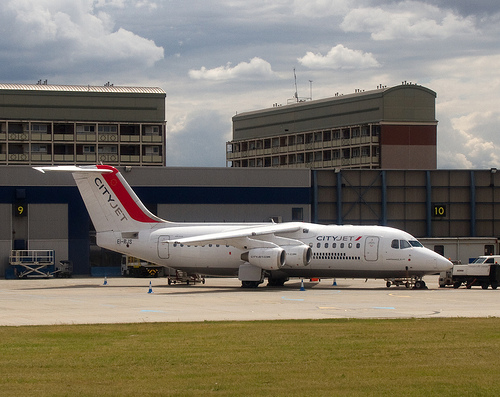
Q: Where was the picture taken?
A: It was taken at the airport.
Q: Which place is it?
A: It is an airport.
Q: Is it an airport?
A: Yes, it is an airport.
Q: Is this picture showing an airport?
A: Yes, it is showing an airport.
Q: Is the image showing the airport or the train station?
A: It is showing the airport.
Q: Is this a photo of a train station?
A: No, the picture is showing an airport.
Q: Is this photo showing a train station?
A: No, the picture is showing an airport.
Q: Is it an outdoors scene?
A: Yes, it is outdoors.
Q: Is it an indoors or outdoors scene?
A: It is outdoors.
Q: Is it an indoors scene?
A: No, it is outdoors.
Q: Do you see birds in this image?
A: No, there are no birds.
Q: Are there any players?
A: No, there are no players.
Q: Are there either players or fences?
A: No, there are no players or fences.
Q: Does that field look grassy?
A: Yes, the field is grassy.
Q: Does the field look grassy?
A: Yes, the field is grassy.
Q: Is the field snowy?
A: No, the field is grassy.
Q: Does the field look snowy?
A: No, the field is grassy.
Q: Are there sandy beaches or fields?
A: No, there is a field but it is grassy.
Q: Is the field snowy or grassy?
A: The field is grassy.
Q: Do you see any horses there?
A: No, there are no horses.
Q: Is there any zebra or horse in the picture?
A: No, there are no horses or zebras.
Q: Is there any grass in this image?
A: Yes, there is grass.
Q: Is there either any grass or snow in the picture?
A: Yes, there is grass.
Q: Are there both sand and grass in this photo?
A: No, there is grass but no sand.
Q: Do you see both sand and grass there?
A: No, there is grass but no sand.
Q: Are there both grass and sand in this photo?
A: No, there is grass but no sand.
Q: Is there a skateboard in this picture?
A: No, there are no skateboards.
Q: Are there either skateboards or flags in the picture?
A: No, there are no skateboards or flags.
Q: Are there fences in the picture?
A: No, there are no fences.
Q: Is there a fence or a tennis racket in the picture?
A: No, there are no fences or rackets.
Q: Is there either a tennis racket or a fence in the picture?
A: No, there are no fences or rackets.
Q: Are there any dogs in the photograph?
A: No, there are no dogs.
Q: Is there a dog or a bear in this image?
A: No, there are no dogs or bears.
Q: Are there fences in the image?
A: No, there are no fences.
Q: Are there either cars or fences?
A: No, there are no fences or cars.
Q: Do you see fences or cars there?
A: No, there are no fences or cars.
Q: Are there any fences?
A: No, there are no fences.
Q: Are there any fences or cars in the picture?
A: No, there are no fences or cars.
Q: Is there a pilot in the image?
A: No, there are no pilots.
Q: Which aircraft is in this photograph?
A: The aircraft is a jet.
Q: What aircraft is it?
A: The aircraft is a jet.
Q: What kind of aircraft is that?
A: That is a jet.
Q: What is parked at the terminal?
A: The jet is parked at the terminal.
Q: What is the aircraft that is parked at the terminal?
A: The aircraft is a jet.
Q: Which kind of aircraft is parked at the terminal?
A: The aircraft is a jet.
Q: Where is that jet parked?
A: The jet is parked at the terminal.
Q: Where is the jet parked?
A: The jet is parked at the terminal.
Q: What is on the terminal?
A: The jet is on the terminal.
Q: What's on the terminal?
A: The jet is on the terminal.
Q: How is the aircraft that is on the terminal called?
A: The aircraft is a jet.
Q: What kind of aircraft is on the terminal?
A: The aircraft is a jet.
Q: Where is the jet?
A: The jet is on the terminal.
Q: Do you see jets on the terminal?
A: Yes, there is a jet on the terminal.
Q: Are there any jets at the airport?
A: Yes, there is a jet at the airport.